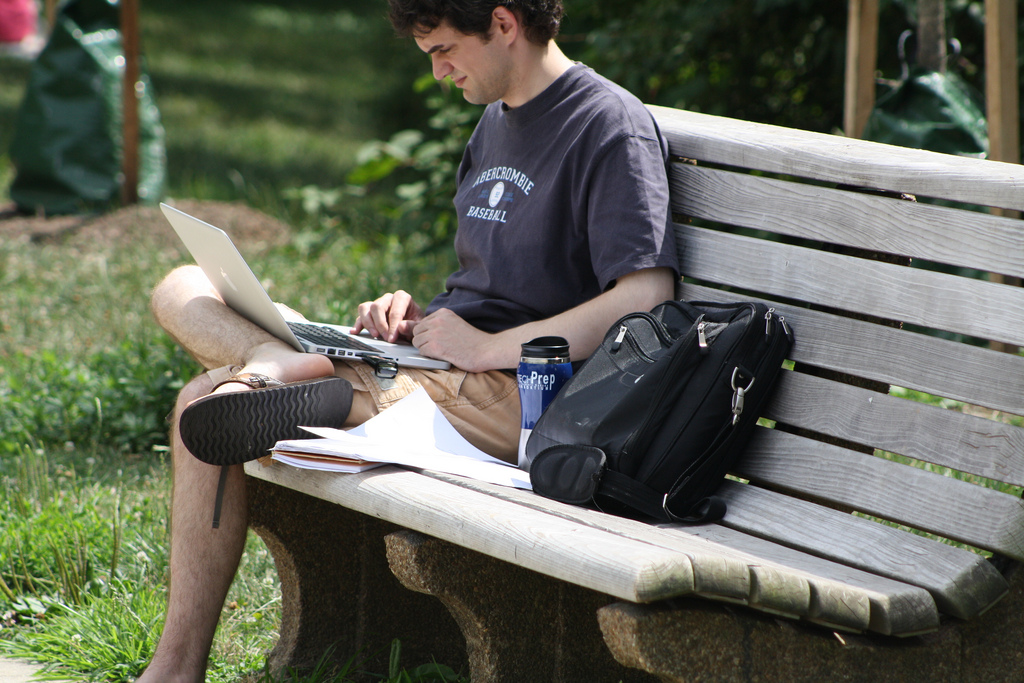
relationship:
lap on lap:
[158, 202, 453, 371] [151, 234, 541, 470]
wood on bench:
[563, 482, 667, 582] [759, 441, 935, 556]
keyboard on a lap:
[296, 299, 361, 347] [158, 202, 453, 371]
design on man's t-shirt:
[463, 164, 541, 225] [435, 60, 680, 331]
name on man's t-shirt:
[466, 209, 508, 229] [435, 60, 680, 331]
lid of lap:
[157, 197, 307, 357] [158, 202, 453, 371]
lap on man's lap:
[158, 202, 453, 371] [317, 365, 508, 424]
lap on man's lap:
[158, 202, 453, 371] [329, 339, 522, 439]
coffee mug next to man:
[517, 336, 574, 473] [118, 4, 687, 681]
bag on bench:
[530, 294, 790, 519] [245, 91, 1015, 673]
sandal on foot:
[178, 376, 362, 461] [202, 350, 343, 387]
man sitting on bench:
[118, 4, 687, 681] [245, 91, 1015, 673]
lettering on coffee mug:
[511, 365, 568, 398] [517, 336, 574, 473]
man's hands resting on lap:
[345, 287, 508, 367] [158, 202, 453, 371]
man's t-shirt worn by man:
[424, 64, 681, 330] [118, 4, 687, 681]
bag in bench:
[530, 294, 790, 519] [245, 91, 1015, 673]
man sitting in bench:
[118, 4, 687, 681] [245, 91, 1015, 673]